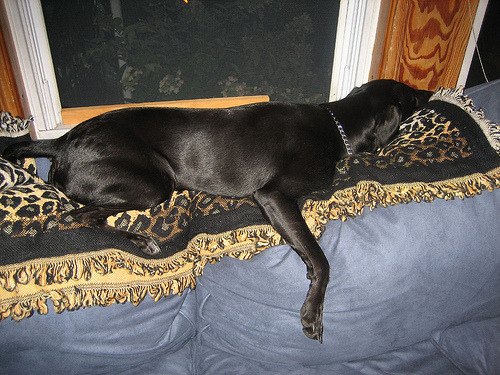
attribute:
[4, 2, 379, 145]
window — white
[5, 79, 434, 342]
dog — black, lying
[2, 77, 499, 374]
fabric — blue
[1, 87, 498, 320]
blanket — black, cheetah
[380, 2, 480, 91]
wall — brown, wooden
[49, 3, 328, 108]
plant — green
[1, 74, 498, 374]
couch — blue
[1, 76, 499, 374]
sofa — blue